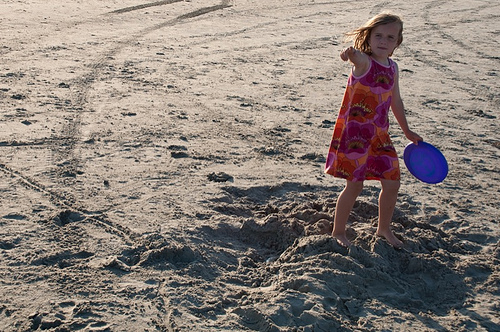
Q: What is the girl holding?
A: A plate.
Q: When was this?
A: Daytime.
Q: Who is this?
A: A girl.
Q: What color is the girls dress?
A: Red.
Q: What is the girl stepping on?
A: Sand.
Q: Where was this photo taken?
A: On a beach.